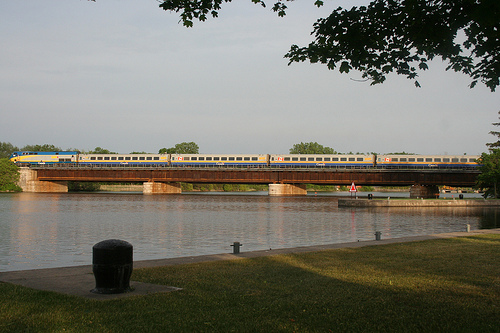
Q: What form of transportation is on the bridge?
A: A train.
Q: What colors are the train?
A: Blue and tan.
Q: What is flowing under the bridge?
A: Water.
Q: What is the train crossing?
A: A bridge.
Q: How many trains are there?
A: 1.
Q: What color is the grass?
A: Green.